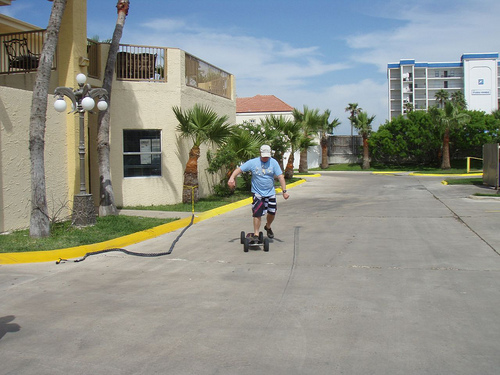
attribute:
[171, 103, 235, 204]
tree — mini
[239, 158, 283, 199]
shirt — blue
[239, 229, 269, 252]
skateboard — black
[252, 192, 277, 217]
shorts — blue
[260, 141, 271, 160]
cap — white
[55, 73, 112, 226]
lamp — grey, outdoor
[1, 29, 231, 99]
railing — brown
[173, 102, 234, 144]
leaves — green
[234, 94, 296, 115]
shingles — red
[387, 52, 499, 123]
building — grey, white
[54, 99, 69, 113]
light — white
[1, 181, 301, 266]
curb — yellow, painted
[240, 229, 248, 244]
wheel — black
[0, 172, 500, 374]
concrete — gray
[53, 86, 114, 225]
post — gray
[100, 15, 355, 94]
cloud — white